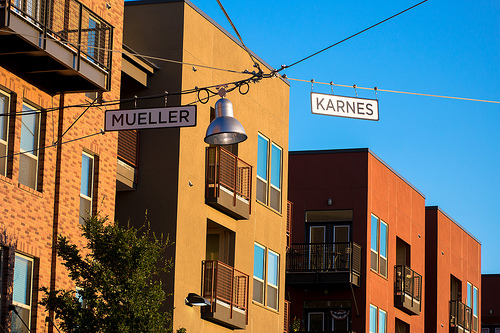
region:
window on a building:
[253, 120, 283, 213]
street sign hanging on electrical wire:
[98, 91, 216, 144]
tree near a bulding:
[86, 200, 176, 325]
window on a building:
[365, 196, 393, 294]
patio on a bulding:
[291, 228, 371, 285]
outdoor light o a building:
[181, 282, 204, 322]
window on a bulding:
[81, 133, 106, 228]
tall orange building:
[433, 188, 496, 328]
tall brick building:
[3, 3, 130, 224]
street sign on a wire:
[297, 59, 394, 139]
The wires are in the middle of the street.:
[0, 0, 498, 160]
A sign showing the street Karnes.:
[306, 87, 376, 117]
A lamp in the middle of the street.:
[200, 85, 245, 147]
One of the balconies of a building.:
[196, 215, 246, 330]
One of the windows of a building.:
[247, 235, 277, 312]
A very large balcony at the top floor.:
[0, 0, 115, 96]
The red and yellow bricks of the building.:
[0, 195, 72, 230]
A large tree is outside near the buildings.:
[30, 191, 175, 327]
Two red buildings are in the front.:
[288, 145, 484, 332]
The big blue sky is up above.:
[291, 2, 498, 146]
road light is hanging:
[165, 13, 281, 168]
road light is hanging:
[177, 95, 298, 232]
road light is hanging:
[190, 71, 270, 162]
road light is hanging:
[197, 106, 283, 187]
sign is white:
[305, 84, 392, 109]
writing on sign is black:
[299, 81, 391, 121]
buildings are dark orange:
[291, 146, 483, 332]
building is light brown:
[143, 3, 295, 330]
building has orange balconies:
[203, 143, 256, 311]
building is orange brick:
[1, 51, 122, 294]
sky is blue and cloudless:
[355, 8, 481, 195]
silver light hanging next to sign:
[215, 96, 249, 148]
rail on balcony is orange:
[210, 149, 261, 193]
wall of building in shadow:
[293, 151, 356, 328]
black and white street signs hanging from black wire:
[93, 99, 203, 134]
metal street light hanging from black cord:
[201, 88, 253, 149]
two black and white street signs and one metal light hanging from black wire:
[80, 48, 402, 152]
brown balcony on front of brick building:
[6, 2, 125, 97]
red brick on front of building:
[66, 98, 98, 144]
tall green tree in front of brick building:
[36, 212, 188, 328]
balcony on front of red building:
[391, 259, 431, 318]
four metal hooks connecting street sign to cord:
[306, 75, 383, 100]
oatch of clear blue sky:
[413, 21, 499, 61]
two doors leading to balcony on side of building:
[300, 211, 355, 273]